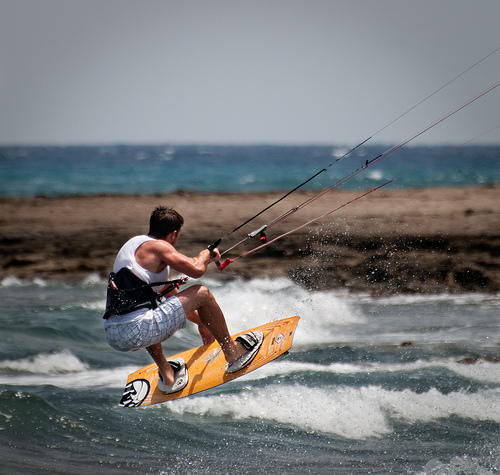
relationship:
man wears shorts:
[100, 187, 240, 378] [102, 307, 187, 347]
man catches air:
[100, 187, 240, 378] [148, 403, 305, 463]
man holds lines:
[100, 187, 240, 378] [257, 118, 403, 259]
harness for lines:
[102, 271, 177, 309] [257, 118, 403, 259]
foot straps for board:
[146, 330, 272, 385] [91, 313, 303, 403]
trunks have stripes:
[102, 307, 187, 347] [157, 314, 181, 324]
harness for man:
[102, 271, 177, 309] [100, 187, 240, 378]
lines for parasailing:
[257, 118, 403, 259] [99, 75, 393, 391]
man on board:
[100, 187, 240, 378] [91, 313, 303, 403]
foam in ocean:
[324, 293, 354, 321] [15, 286, 490, 462]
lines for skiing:
[257, 118, 403, 259] [73, 249, 294, 359]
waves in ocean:
[292, 285, 456, 431] [15, 286, 490, 462]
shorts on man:
[102, 307, 187, 347] [100, 187, 240, 378]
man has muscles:
[100, 187, 240, 378] [163, 245, 199, 274]